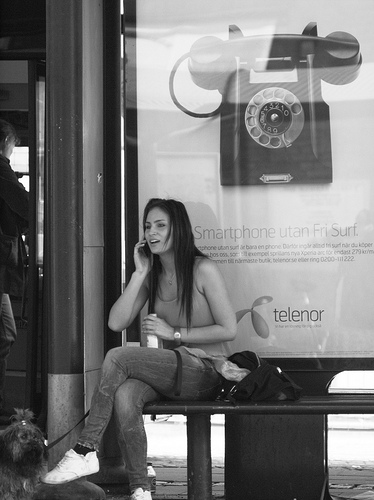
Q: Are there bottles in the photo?
A: Yes, there is a bottle.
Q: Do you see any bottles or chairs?
A: Yes, there is a bottle.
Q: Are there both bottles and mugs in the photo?
A: No, there is a bottle but no mugs.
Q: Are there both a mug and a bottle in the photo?
A: No, there is a bottle but no mugs.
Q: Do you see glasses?
A: No, there are no glasses.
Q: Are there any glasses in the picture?
A: No, there are no glasses.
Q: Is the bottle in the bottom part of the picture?
A: Yes, the bottle is in the bottom of the image.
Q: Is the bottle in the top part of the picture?
A: No, the bottle is in the bottom of the image.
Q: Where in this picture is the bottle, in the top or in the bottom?
A: The bottle is in the bottom of the image.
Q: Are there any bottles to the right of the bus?
A: Yes, there is a bottle to the right of the bus.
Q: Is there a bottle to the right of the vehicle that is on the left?
A: Yes, there is a bottle to the right of the bus.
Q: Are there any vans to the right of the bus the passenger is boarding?
A: No, there is a bottle to the right of the bus.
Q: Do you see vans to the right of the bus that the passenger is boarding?
A: No, there is a bottle to the right of the bus.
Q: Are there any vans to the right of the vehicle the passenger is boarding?
A: No, there is a bottle to the right of the bus.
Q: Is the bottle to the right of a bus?
A: Yes, the bottle is to the right of a bus.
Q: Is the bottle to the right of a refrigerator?
A: No, the bottle is to the right of a bus.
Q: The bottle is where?
A: The bottle is on the ground.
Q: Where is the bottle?
A: The bottle is on the ground.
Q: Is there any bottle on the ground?
A: Yes, there is a bottle on the ground.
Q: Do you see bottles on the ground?
A: Yes, there is a bottle on the ground.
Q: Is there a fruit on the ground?
A: No, there is a bottle on the ground.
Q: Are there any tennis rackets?
A: No, there are no tennis rackets.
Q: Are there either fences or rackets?
A: No, there are no rackets or fences.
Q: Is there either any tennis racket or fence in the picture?
A: No, there are no rackets or fences.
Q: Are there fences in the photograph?
A: No, there are no fences.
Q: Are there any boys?
A: No, there are no boys.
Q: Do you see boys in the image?
A: No, there are no boys.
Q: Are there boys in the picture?
A: No, there are no boys.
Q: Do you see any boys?
A: No, there are no boys.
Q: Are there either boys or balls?
A: No, there are no boys or balls.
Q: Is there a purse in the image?
A: Yes, there is a purse.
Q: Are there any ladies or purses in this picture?
A: Yes, there is a purse.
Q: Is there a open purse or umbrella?
A: Yes, there is an open purse.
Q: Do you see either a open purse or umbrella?
A: Yes, there is an open purse.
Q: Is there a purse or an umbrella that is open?
A: Yes, the purse is open.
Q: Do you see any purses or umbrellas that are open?
A: Yes, the purse is open.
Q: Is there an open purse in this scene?
A: Yes, there is an open purse.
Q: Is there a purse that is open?
A: Yes, there is a purse that is open.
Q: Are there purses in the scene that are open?
A: Yes, there is a purse that is open.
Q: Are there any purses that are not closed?
A: Yes, there is a open purse.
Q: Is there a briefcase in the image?
A: No, there are no briefcases.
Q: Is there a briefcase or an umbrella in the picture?
A: No, there are no briefcases or umbrellas.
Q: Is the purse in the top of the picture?
A: No, the purse is in the bottom of the image.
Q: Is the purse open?
A: Yes, the purse is open.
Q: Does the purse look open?
A: Yes, the purse is open.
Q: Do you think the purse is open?
A: Yes, the purse is open.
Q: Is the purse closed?
A: No, the purse is open.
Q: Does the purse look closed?
A: No, the purse is open.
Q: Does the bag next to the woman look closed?
A: No, the purse is open.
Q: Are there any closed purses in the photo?
A: No, there is a purse but it is open.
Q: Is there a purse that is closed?
A: No, there is a purse but it is open.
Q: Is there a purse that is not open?
A: No, there is a purse but it is open.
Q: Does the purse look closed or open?
A: The purse is open.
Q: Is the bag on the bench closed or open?
A: The purse is open.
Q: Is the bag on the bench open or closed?
A: The purse is open.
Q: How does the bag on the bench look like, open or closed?
A: The purse is open.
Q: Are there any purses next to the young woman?
A: Yes, there is a purse next to the woman.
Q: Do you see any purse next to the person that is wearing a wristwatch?
A: Yes, there is a purse next to the woman.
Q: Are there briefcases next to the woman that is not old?
A: No, there is a purse next to the woman.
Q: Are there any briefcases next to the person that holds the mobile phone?
A: No, there is a purse next to the woman.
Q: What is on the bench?
A: The purse is on the bench.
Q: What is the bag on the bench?
A: The bag is a purse.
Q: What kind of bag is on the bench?
A: The bag is a purse.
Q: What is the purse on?
A: The purse is on the bench.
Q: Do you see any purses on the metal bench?
A: Yes, there is a purse on the bench.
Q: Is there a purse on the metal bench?
A: Yes, there is a purse on the bench.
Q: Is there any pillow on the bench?
A: No, there is a purse on the bench.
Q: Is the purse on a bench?
A: Yes, the purse is on a bench.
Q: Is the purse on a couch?
A: No, the purse is on a bench.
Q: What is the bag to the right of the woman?
A: The bag is a purse.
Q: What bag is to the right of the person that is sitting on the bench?
A: The bag is a purse.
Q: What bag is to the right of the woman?
A: The bag is a purse.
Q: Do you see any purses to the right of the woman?
A: Yes, there is a purse to the right of the woman.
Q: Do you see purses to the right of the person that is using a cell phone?
A: Yes, there is a purse to the right of the woman.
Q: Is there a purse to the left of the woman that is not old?
A: No, the purse is to the right of the woman.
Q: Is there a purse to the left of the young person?
A: No, the purse is to the right of the woman.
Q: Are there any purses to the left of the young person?
A: No, the purse is to the right of the woman.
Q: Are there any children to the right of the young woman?
A: No, there is a purse to the right of the woman.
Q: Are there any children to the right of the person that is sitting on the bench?
A: No, there is a purse to the right of the woman.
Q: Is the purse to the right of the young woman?
A: Yes, the purse is to the right of the woman.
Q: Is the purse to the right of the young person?
A: Yes, the purse is to the right of the woman.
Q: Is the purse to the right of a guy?
A: No, the purse is to the right of the woman.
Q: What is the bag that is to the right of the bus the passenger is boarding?
A: The bag is a purse.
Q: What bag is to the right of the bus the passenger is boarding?
A: The bag is a purse.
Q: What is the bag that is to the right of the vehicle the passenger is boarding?
A: The bag is a purse.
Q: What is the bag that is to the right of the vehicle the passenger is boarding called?
A: The bag is a purse.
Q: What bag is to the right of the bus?
A: The bag is a purse.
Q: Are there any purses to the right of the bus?
A: Yes, there is a purse to the right of the bus.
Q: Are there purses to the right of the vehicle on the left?
A: Yes, there is a purse to the right of the bus.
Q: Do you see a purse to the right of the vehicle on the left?
A: Yes, there is a purse to the right of the bus.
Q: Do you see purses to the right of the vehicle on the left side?
A: Yes, there is a purse to the right of the bus.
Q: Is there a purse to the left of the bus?
A: No, the purse is to the right of the bus.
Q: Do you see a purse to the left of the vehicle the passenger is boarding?
A: No, the purse is to the right of the bus.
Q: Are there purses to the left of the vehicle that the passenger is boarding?
A: No, the purse is to the right of the bus.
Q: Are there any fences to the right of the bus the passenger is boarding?
A: No, there is a purse to the right of the bus.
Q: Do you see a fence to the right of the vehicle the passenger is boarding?
A: No, there is a purse to the right of the bus.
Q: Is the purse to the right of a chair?
A: No, the purse is to the right of a bus.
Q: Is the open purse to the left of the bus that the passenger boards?
A: No, the purse is to the right of the bus.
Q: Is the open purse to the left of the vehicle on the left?
A: No, the purse is to the right of the bus.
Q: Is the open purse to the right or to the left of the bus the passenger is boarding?
A: The purse is to the right of the bus.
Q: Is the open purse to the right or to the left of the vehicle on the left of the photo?
A: The purse is to the right of the bus.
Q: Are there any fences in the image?
A: No, there are no fences.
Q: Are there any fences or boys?
A: No, there are no fences or boys.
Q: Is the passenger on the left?
A: Yes, the passenger is on the left of the image.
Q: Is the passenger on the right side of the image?
A: No, the passenger is on the left of the image.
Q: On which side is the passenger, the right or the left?
A: The passenger is on the left of the image.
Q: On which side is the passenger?
A: The passenger is on the left of the image.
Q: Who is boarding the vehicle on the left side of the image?
A: The passenger is boarding the bus.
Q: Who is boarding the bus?
A: The passenger is boarding the bus.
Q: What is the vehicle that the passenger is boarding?
A: The vehicle is a bus.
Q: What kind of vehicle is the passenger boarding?
A: The passenger is boarding the bus.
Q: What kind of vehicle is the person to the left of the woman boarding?
A: The passenger is boarding the bus.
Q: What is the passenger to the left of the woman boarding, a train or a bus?
A: The passenger is boarding a bus.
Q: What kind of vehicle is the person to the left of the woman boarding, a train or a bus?
A: The passenger is boarding a bus.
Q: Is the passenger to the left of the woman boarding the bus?
A: Yes, the passenger is boarding the bus.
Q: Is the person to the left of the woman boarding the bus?
A: Yes, the passenger is boarding the bus.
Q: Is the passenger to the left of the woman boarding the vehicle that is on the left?
A: Yes, the passenger is boarding the bus.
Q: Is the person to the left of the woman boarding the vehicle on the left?
A: Yes, the passenger is boarding the bus.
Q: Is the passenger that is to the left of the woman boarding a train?
A: No, the passenger is boarding the bus.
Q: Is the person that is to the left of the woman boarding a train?
A: No, the passenger is boarding the bus.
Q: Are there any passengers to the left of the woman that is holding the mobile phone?
A: Yes, there is a passenger to the left of the woman.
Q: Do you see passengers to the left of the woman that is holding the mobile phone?
A: Yes, there is a passenger to the left of the woman.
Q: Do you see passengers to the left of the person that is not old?
A: Yes, there is a passenger to the left of the woman.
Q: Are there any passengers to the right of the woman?
A: No, the passenger is to the left of the woman.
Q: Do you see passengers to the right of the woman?
A: No, the passenger is to the left of the woman.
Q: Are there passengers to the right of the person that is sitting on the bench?
A: No, the passenger is to the left of the woman.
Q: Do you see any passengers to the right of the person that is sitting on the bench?
A: No, the passenger is to the left of the woman.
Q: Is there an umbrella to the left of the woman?
A: No, there is a passenger to the left of the woman.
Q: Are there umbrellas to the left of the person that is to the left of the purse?
A: No, there is a passenger to the left of the woman.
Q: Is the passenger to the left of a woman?
A: Yes, the passenger is to the left of a woman.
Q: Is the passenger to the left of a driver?
A: No, the passenger is to the left of a woman.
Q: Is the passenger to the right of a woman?
A: No, the passenger is to the left of a woman.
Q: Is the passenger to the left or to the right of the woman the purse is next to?
A: The passenger is to the left of the woman.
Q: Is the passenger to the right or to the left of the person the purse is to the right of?
A: The passenger is to the left of the woman.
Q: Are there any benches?
A: Yes, there is a bench.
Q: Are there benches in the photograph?
A: Yes, there is a bench.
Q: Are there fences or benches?
A: Yes, there is a bench.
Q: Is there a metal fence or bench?
A: Yes, there is a metal bench.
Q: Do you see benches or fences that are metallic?
A: Yes, the bench is metallic.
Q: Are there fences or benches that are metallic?
A: Yes, the bench is metallic.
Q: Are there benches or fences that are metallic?
A: Yes, the bench is metallic.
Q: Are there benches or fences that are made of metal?
A: Yes, the bench is made of metal.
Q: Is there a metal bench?
A: Yes, there is a bench that is made of metal.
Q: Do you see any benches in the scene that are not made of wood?
A: Yes, there is a bench that is made of metal.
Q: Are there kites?
A: No, there are no kites.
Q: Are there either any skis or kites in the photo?
A: No, there are no kites or skis.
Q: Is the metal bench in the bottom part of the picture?
A: Yes, the bench is in the bottom of the image.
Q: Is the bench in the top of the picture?
A: No, the bench is in the bottom of the image.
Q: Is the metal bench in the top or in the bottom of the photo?
A: The bench is in the bottom of the image.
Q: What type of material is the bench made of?
A: The bench is made of metal.